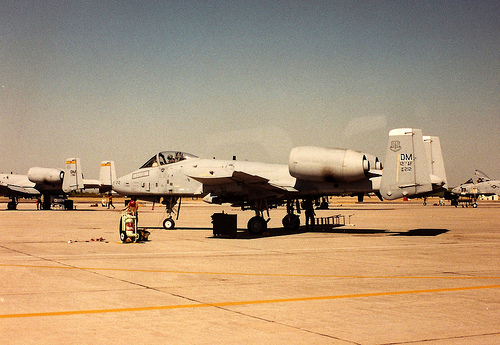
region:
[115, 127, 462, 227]
plane sitting on the tarmac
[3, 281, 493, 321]
long yellow line painted on the ground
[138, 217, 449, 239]
shadow from the plane on the ground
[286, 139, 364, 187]
large jet engine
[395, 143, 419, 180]
writing on the tail of the plane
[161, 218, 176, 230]
small front wheel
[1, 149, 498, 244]
three planes on the tarmac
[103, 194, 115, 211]
person walking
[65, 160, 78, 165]
yellow stripe on the top of the tail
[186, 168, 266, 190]
wing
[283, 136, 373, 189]
engine on a jet airplane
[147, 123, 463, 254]
jet airplane with shadow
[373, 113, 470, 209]
tail wing of an airplane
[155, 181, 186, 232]
jet airplane landing gear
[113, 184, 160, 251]
person with dolly cart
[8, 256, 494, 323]
yellow lines on concrete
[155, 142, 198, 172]
pilot in cockpit of jet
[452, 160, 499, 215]
open jet cockpit dome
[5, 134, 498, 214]
three jet airplanes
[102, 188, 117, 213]
person walking in distance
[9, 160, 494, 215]
Four airplanes on the runway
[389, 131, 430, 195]
Tail piece of jet is silver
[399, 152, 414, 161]
Small letters on tail piece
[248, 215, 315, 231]
Wheels of airplane are black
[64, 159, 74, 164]
Small yellow strip on back of airplane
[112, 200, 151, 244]
Person alongside of airplane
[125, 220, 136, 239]
Medium sized red container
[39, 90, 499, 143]
Sky is grey blue color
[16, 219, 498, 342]
Airplanes are sitting on landing strip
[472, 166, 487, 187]
Cockpit of airplane is opened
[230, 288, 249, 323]
the line is yellow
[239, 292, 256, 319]
the line is yellow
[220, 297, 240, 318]
the line is yellow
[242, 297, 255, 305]
the line is yellow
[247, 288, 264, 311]
the line is yellow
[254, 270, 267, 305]
the line is yellow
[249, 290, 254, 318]
the line is yellow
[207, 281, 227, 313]
the line is yellow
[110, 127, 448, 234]
A fighter jet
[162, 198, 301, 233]
landing gear of a fighter jet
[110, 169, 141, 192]
nose of a fighter jet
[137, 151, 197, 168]
cockpit of a fighter jet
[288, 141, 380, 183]
engines of a fighter jet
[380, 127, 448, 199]
tail of a fighter jet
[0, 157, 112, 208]
A grey fighter jet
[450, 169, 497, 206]
A grey fighter jet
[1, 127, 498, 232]
three grey fighter jets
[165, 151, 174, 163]
a fighter jet pilot